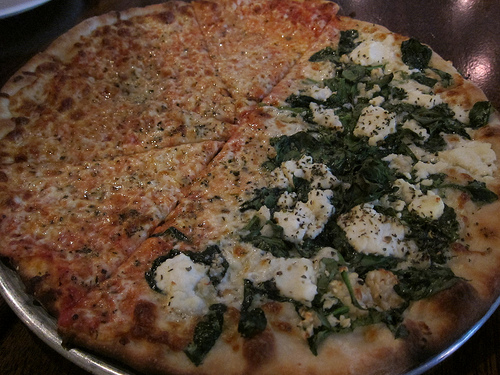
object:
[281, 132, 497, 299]
piece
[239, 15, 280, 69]
pizza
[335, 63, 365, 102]
spinach on it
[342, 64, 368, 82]
spinach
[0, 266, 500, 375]
pizza tray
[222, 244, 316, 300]
ricotta cheese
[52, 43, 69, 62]
part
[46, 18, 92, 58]
crust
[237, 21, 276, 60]
cheese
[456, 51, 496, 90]
reflection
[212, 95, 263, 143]
center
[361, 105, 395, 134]
spices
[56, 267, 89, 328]
tomato sauce